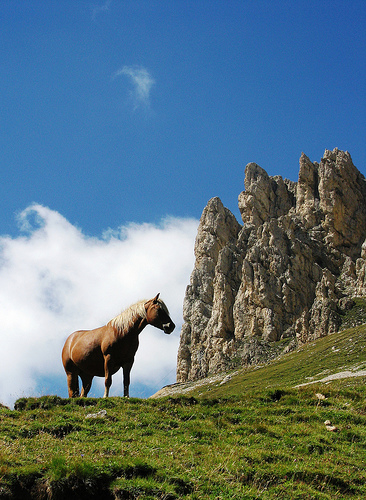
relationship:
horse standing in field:
[36, 289, 182, 406] [12, 357, 364, 498]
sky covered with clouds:
[1, 1, 362, 279] [4, 198, 191, 391]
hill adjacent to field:
[205, 181, 358, 316] [9, 339, 364, 481]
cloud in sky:
[7, 214, 177, 306] [0, 203, 223, 405]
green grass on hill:
[145, 398, 331, 480] [18, 390, 255, 498]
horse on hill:
[59, 290, 176, 397] [72, 358, 275, 454]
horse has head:
[59, 290, 176, 397] [140, 287, 180, 338]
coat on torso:
[76, 337, 97, 349] [71, 326, 98, 371]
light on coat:
[67, 332, 78, 358] [70, 332, 123, 369]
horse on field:
[59, 290, 176, 397] [1, 389, 364, 462]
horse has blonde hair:
[59, 290, 176, 397] [101, 295, 187, 342]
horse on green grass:
[59, 290, 176, 397] [0, 321, 365, 428]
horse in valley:
[59, 290, 176, 397] [4, 201, 362, 494]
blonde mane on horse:
[110, 294, 151, 338] [61, 297, 184, 393]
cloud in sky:
[103, 55, 168, 130] [2, 0, 362, 390]